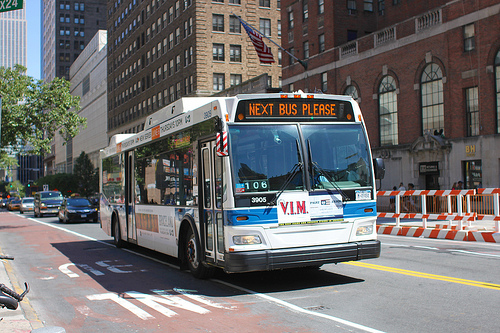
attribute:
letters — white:
[60, 253, 222, 318]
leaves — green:
[0, 83, 19, 133]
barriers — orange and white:
[378, 181, 498, 242]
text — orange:
[245, 100, 337, 117]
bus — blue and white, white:
[93, 84, 384, 287]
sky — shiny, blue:
[18, 26, 49, 72]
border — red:
[378, 195, 494, 215]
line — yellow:
[397, 252, 497, 312]